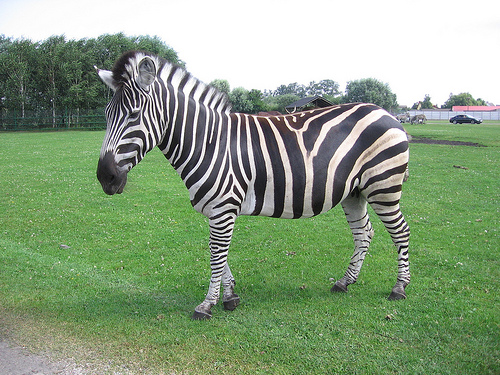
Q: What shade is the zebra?
A: White and black.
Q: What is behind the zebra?
A: Trees.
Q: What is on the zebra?
A: Stripes.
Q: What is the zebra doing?
A: Standing there.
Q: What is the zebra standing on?
A: On four legs.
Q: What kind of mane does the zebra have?
A: A medium length mane.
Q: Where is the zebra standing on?
A: On green grass.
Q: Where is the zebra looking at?
A: To the left.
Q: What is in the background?
A: There are trees.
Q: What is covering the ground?
A: Green grass.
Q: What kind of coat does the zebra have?
A: It's black and white.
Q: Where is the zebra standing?
A: On grass.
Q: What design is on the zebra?
A: Black and white stripes.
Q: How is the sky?
A: Oddly bright and white.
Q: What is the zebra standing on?
A: Large open grass area.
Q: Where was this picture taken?
A: The zoo.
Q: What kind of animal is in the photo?
A: A zebra.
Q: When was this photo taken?
A: Yesterday.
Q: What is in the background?
A: A lawn.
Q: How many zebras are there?
A: One.